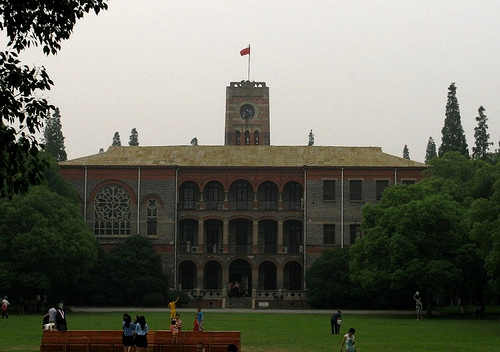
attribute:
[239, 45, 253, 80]
flag — red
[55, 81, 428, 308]
building — large, old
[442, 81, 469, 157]
tree — tall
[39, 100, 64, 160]
tree — tall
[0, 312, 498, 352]
grass — green, lush, large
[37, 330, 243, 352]
bench — wooden, red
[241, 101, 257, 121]
clock — black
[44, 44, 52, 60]
leaf — green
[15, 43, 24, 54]
leaf — green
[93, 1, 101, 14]
leaf — green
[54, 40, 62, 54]
leaf — green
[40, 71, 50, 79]
leaf — green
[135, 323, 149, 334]
top — blue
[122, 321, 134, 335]
top — blue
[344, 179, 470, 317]
tree — green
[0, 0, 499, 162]
sky — gray, clear, white, bright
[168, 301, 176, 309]
shirt — yellow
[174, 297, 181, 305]
arm — raised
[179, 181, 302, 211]
balcony — large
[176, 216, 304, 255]
balcony — large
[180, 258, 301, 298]
balcony — large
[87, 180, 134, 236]
window — big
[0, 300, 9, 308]
t-shirt — white